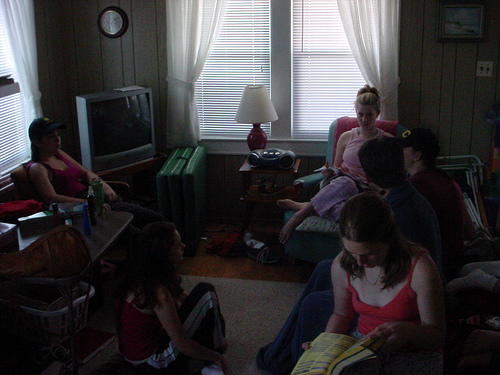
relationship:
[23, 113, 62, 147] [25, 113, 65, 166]
cap on head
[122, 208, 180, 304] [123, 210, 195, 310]
hair on head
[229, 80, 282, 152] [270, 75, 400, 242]
lamp next to girl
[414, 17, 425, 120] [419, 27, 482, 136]
line on wall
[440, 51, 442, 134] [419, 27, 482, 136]
line on wall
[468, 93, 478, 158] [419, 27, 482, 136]
line on wall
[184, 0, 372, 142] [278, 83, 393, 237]
window behind girl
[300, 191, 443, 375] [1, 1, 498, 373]
girl in photo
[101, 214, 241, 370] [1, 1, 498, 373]
girl in photo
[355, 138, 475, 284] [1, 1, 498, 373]
people in photo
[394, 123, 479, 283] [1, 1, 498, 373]
man in photo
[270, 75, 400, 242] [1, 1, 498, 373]
girl in photo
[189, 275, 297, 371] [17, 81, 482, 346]
carpet next to people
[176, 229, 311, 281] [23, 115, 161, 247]
floor under girl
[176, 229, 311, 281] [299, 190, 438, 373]
floor under person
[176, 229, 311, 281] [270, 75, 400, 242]
floor under girl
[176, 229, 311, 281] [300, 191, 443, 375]
floor under girl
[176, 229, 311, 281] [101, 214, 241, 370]
floor under girl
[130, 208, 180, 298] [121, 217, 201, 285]
hair on head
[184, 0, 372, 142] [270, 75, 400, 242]
window behind girl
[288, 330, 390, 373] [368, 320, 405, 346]
book in hand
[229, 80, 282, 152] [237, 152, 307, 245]
lamp on table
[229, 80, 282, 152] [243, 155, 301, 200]
lamp on a table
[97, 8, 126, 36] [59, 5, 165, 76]
clock on a wall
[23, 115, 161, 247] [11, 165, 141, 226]
girl sitting in a chair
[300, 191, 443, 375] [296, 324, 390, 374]
girl looking at book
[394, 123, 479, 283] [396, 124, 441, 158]
man wearing a ball cap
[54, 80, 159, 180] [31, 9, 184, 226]
television in a corner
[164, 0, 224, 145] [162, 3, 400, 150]
curtain on window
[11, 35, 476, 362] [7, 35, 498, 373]
people in room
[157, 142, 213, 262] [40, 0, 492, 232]
tables near wall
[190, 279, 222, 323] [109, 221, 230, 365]
knee on girl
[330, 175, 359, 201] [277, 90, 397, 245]
knee on girl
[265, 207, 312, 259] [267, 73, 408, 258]
foot on girl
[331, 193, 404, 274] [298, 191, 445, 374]
head on girl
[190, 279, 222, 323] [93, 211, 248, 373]
knee on girl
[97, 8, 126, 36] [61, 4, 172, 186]
clock on wall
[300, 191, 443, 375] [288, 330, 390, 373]
girl looks at book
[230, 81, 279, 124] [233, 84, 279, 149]
lamp shade on lamp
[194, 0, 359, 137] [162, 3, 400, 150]
blinds on window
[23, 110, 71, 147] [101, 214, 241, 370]
cap on girl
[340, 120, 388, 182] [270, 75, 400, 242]
shirt on girl